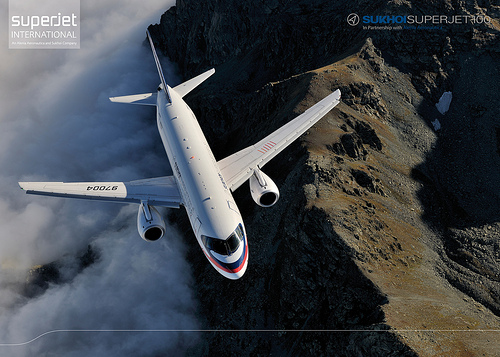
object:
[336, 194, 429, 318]
dirt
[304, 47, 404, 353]
peak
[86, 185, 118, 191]
97004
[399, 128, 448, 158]
ground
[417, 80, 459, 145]
stones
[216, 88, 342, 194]
wing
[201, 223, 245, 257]
windshield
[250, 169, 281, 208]
engine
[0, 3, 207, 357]
clouds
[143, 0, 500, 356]
mountain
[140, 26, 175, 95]
tail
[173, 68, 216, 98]
tail fin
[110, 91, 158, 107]
tail fin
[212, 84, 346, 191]
cakes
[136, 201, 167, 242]
engine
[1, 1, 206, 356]
sky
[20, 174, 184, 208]
wing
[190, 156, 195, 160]
light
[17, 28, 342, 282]
airplane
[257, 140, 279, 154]
stripes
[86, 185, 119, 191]
numbers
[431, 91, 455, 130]
snow